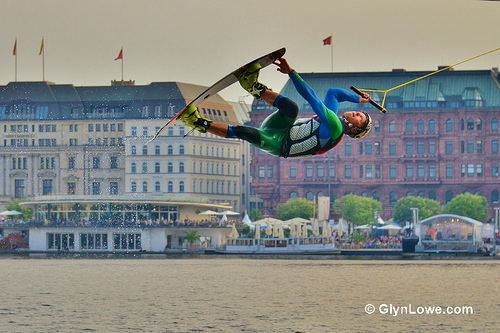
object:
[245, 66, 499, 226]
building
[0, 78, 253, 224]
building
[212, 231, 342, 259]
boat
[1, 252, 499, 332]
water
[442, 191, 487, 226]
trees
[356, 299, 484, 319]
trademark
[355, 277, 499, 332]
corner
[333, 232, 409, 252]
people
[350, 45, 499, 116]
rope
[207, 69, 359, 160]
wetsuit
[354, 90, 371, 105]
hand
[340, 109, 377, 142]
helmet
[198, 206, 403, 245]
patio umbrellas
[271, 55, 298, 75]
left hand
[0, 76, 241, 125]
roof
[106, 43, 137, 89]
flag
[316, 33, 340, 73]
flag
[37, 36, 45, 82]
flag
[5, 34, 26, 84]
flag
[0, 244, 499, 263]
covered area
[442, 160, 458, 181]
window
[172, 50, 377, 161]
man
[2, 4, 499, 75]
air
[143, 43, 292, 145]
ski